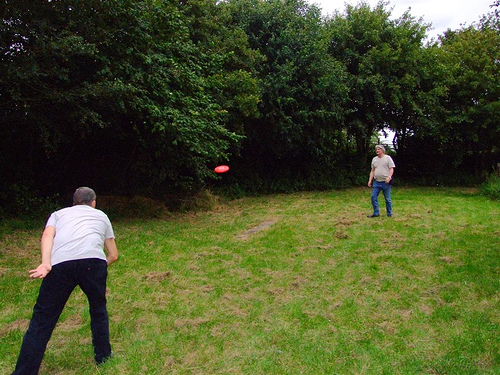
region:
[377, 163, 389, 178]
man wearing brown shirt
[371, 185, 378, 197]
man wearing blue jeans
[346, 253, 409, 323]
green grass in field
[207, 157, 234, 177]
red frisby in air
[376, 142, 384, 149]
man has grey hair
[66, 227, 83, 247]
man wearing white shirt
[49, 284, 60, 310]
man wearing blue sweats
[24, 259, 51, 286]
man hand behind back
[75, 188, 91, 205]
man hair dark grey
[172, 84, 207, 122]
trees on side of field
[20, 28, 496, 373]
The people are standing in the grass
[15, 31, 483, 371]
The people are playing with a frisbee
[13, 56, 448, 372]
A person is wearing dark pants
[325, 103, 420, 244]
A person is wearing blue jeans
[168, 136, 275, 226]
A frisbee is flying in the air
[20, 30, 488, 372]
The people are close to some bushes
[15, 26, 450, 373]
The people are enjoying their day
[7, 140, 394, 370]
Two men playing a game.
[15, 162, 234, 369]
A man playing frisbee.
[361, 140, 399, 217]
A man waiting to catch a frisbee.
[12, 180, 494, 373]
A green yard.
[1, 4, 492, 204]
Trees lining the edge of a yard.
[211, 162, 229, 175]
A red Frisbee flying through the air.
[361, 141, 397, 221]
A man wearing jeans.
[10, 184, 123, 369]
A man wearing a white shirt.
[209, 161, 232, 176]
A red disc flying through the air.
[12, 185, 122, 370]
Man with his arm behind his back.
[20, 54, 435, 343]
two older men playing frisbee on the grass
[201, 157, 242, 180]
red frisbee in the air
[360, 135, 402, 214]
man wearing tan shirt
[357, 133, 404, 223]
man wearing blue jeans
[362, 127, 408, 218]
man has white hair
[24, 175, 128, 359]
man wearing black jeans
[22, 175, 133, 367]
man wearing white shirt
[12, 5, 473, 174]
trees are full of leaves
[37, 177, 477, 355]
grass is green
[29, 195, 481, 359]
grass has brown patches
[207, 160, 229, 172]
a red Frisbee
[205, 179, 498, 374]
part of a green and brown grassy yard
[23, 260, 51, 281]
the hand of a man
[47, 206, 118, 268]
a man's white shirt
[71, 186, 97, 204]
a man's short cut gray hair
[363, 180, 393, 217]
a man's blue jean pants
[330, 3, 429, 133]
a large green tree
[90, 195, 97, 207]
the ear of a man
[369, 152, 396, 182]
a man's gray shirt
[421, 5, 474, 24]
part of a white sky